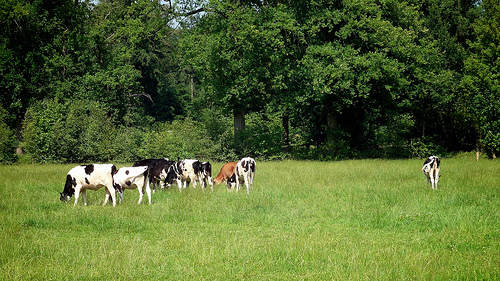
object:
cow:
[59, 162, 117, 208]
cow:
[212, 160, 235, 186]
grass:
[3, 160, 498, 275]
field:
[4, 158, 500, 281]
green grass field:
[0, 159, 496, 281]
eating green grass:
[54, 111, 290, 249]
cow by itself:
[420, 153, 445, 193]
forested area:
[6, 3, 498, 160]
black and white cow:
[155, 158, 214, 194]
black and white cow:
[224, 157, 257, 195]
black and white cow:
[106, 164, 153, 208]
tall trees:
[83, 1, 184, 161]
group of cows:
[66, 154, 256, 208]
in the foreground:
[48, 146, 145, 223]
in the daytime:
[1, 1, 494, 281]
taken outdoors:
[0, 0, 498, 281]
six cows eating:
[62, 155, 255, 207]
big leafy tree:
[180, 1, 302, 155]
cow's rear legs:
[243, 163, 251, 194]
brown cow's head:
[207, 175, 223, 189]